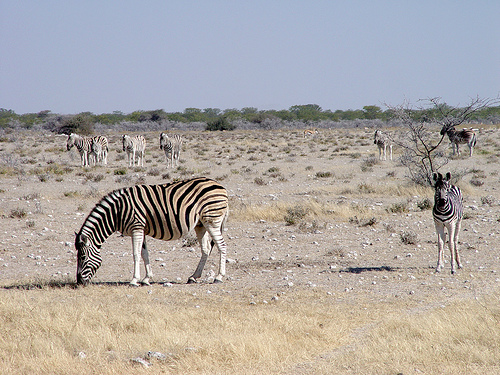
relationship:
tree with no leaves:
[390, 98, 443, 176] [373, 103, 378, 113]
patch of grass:
[34, 302, 93, 329] [253, 203, 343, 219]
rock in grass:
[248, 253, 261, 264] [253, 203, 343, 219]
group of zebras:
[60, 122, 188, 162] [69, 131, 115, 159]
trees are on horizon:
[115, 103, 327, 137] [68, 66, 498, 114]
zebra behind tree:
[433, 118, 482, 156] [390, 98, 443, 176]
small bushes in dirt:
[284, 199, 318, 230] [299, 235, 358, 250]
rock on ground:
[248, 253, 261, 264] [243, 253, 428, 324]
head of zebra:
[63, 230, 110, 286] [60, 169, 225, 310]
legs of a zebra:
[127, 228, 234, 283] [60, 169, 225, 310]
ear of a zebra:
[79, 232, 91, 248] [60, 169, 225, 310]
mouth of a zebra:
[83, 280, 95, 292] [60, 169, 225, 310]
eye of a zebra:
[78, 253, 87, 261] [60, 169, 225, 310]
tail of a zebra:
[221, 202, 235, 240] [60, 169, 225, 310]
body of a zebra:
[104, 172, 229, 230] [60, 169, 225, 310]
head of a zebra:
[63, 230, 110, 286] [60, 169, 225, 310]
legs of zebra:
[127, 228, 234, 283] [60, 169, 225, 310]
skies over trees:
[37, 20, 483, 91] [115, 103, 327, 137]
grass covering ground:
[253, 203, 343, 219] [243, 253, 428, 324]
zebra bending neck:
[60, 169, 225, 310] [86, 184, 117, 246]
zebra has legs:
[419, 169, 474, 276] [428, 218, 464, 266]